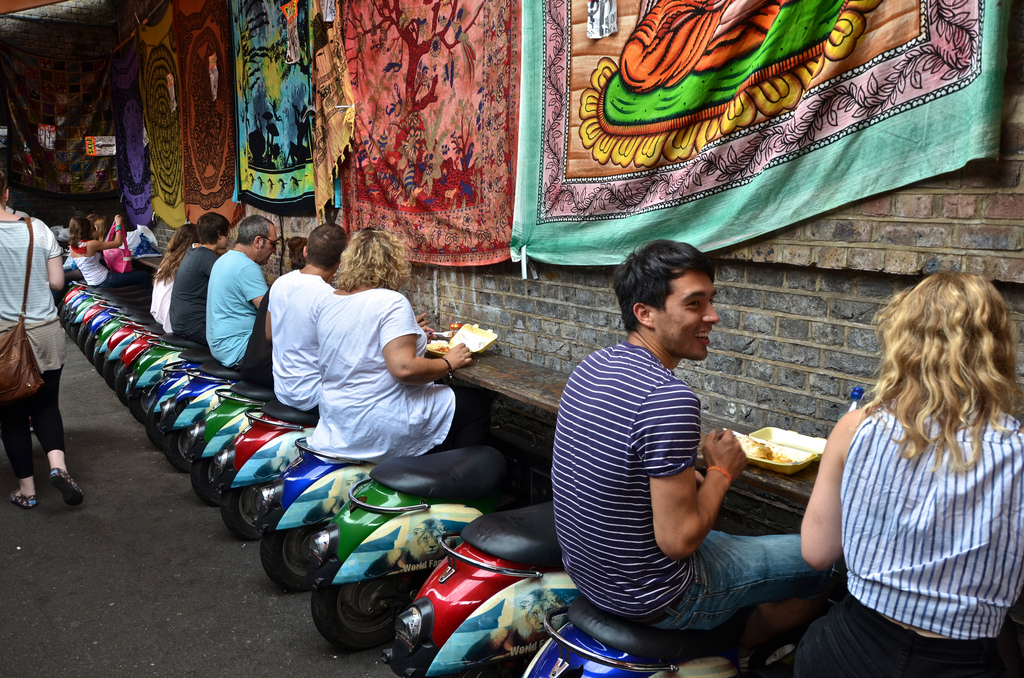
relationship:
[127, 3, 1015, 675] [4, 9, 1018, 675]
wall on side of building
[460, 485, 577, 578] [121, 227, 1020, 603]
seat under counter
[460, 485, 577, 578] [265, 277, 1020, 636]
seat under counter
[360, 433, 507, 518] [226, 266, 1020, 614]
seat under counter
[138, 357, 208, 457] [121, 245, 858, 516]
motorcycle seat under counter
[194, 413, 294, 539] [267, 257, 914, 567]
motorcycle seat under counter